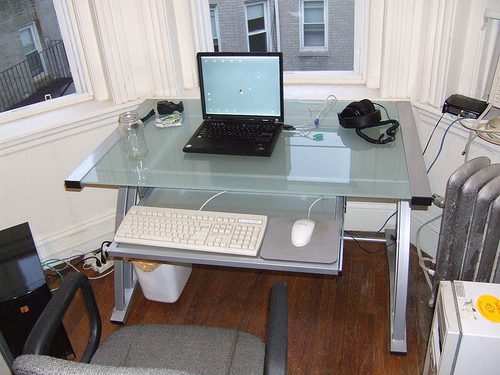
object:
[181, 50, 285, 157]
laptop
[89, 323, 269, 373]
cushion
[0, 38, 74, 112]
balcony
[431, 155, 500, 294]
radiator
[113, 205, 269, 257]
keyboard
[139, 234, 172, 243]
keys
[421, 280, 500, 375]
processing unit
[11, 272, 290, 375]
chair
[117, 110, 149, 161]
clear jar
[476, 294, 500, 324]
sticker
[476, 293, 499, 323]
yellow sticker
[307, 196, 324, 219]
mouse wire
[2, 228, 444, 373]
floor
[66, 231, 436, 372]
grain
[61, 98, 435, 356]
desk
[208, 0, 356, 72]
window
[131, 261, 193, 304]
can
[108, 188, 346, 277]
shelf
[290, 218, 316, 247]
mouse